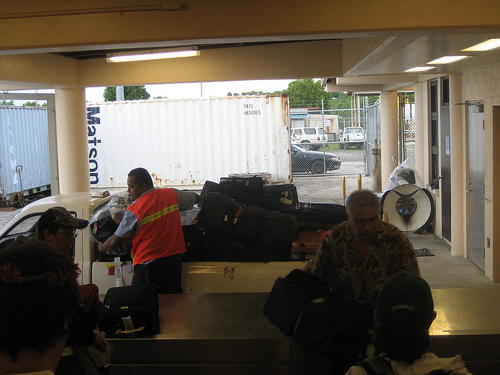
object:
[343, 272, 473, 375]
person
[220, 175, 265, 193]
luggage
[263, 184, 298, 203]
luggage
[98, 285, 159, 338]
luggage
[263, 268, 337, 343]
luggage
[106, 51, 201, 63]
light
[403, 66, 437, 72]
light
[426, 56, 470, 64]
light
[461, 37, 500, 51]
light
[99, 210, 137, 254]
arm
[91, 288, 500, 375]
counter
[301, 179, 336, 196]
ground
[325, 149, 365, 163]
street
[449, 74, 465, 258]
pillar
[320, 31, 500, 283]
building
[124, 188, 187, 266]
outfit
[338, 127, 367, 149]
car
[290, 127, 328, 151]
car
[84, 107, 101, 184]
lettering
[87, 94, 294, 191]
container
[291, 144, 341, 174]
car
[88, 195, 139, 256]
luggage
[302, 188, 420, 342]
man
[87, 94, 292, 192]
truck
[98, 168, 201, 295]
man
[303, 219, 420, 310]
shirt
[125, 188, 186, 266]
vest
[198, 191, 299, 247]
luggage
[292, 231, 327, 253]
luggage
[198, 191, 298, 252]
bag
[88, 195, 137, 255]
bag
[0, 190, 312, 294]
truck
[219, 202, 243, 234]
strap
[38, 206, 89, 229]
hat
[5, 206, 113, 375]
person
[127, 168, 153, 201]
head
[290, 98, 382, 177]
fence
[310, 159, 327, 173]
tire